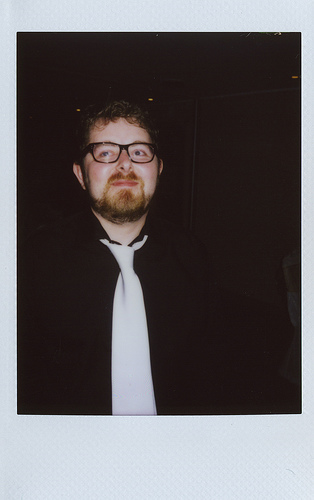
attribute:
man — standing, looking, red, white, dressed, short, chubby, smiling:
[61, 112, 240, 417]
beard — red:
[108, 169, 150, 218]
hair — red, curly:
[94, 97, 147, 124]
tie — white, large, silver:
[102, 254, 157, 414]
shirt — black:
[188, 285, 247, 360]